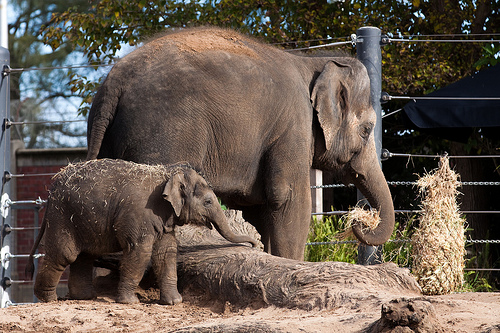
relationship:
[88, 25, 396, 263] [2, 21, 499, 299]
elephant behind fence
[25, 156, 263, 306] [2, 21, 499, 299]
elephant behind fence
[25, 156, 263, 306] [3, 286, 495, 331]
elephant standing on ground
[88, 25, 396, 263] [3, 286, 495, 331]
elephant standing on ground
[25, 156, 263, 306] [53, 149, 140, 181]
elephant has back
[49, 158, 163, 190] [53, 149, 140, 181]
straw on back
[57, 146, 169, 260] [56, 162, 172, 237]
body of elephant